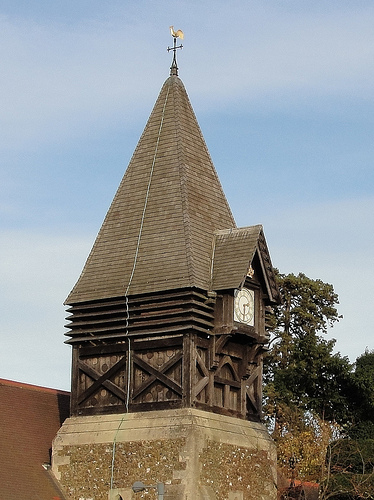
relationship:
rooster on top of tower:
[167, 21, 184, 42] [153, 26, 200, 93]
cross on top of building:
[164, 26, 185, 67] [75, 98, 256, 499]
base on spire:
[62, 412, 307, 487] [49, 35, 280, 496]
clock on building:
[233, 286, 254, 326] [49, 26, 280, 498]